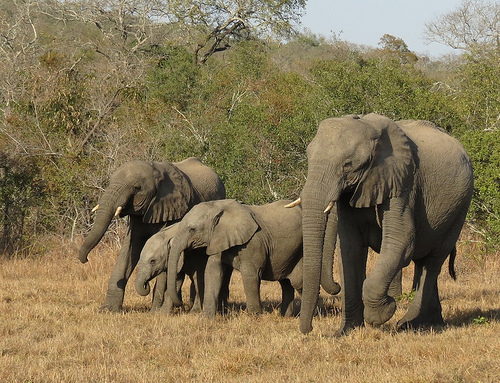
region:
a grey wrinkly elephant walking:
[77, 156, 224, 316]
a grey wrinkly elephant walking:
[130, 220, 207, 319]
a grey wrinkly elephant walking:
[168, 195, 318, 323]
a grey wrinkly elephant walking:
[287, 113, 465, 328]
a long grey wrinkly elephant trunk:
[77, 180, 134, 263]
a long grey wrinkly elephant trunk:
[133, 255, 155, 296]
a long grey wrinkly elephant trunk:
[170, 223, 188, 307]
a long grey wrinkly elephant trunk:
[320, 201, 340, 299]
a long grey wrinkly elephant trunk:
[302, 141, 327, 331]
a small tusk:
[287, 197, 302, 208]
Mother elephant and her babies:
[55, 87, 461, 353]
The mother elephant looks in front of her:
[300, 100, 472, 364]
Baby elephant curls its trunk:
[135, 236, 182, 318]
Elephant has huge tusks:
[283, 185, 348, 217]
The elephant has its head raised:
[60, 165, 245, 235]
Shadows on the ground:
[425, 296, 495, 336]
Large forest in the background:
[65, 15, 346, 91]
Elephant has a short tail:
[440, 206, 460, 276]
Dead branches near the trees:
[6, 4, 99, 85]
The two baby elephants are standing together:
[132, 217, 327, 331]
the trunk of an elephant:
[296, 179, 319, 341]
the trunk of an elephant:
[72, 206, 112, 267]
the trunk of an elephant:
[161, 244, 188, 311]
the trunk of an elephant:
[128, 272, 155, 298]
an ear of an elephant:
[148, 163, 188, 228]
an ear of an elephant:
[207, 203, 262, 253]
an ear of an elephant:
[359, 127, 416, 205]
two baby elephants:
[128, 213, 284, 320]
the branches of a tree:
[191, 8, 241, 50]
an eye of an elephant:
[339, 153, 359, 174]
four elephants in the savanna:
[65, 95, 480, 346]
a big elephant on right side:
[285, 101, 471, 346]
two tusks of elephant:
[277, 187, 343, 227]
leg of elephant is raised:
[350, 222, 414, 337]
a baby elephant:
[125, 211, 195, 327]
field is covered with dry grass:
[9, 252, 496, 379]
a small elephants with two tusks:
[63, 137, 185, 266]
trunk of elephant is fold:
[123, 227, 163, 304]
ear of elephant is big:
[343, 105, 421, 220]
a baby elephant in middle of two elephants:
[63, 128, 308, 325]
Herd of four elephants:
[79, 108, 474, 326]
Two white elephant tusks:
[278, 186, 344, 225]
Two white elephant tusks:
[85, 195, 126, 228]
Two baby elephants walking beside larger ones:
[122, 193, 317, 320]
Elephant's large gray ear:
[359, 115, 424, 211]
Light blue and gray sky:
[150, 3, 490, 52]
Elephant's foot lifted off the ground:
[344, 275, 410, 339]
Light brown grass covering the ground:
[15, 257, 497, 381]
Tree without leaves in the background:
[422, 1, 499, 61]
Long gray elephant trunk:
[292, 193, 327, 340]